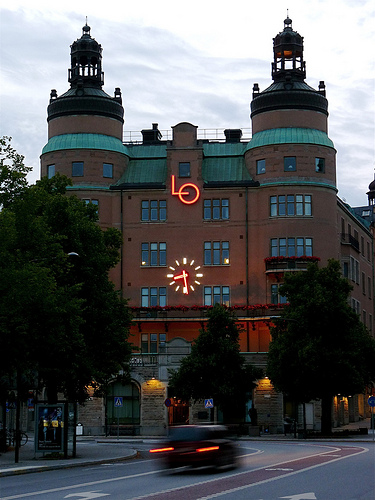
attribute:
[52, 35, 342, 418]
building — orange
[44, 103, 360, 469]
building — orange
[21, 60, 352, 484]
building — orange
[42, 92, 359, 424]
building — orange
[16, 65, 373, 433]
building — orange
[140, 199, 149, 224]
window — small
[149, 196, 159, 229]
window — small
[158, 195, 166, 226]
window — small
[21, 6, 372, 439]
building — orange, large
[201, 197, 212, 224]
window — small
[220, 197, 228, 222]
window — small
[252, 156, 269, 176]
window — small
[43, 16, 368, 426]
building — large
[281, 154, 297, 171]
window — small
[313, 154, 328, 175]
window — small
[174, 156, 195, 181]
window — small, large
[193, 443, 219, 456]
light — trailing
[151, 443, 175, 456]
light — trailing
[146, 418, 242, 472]
vehicle — red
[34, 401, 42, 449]
border — blue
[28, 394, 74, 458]
poster — large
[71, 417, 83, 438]
trash can — white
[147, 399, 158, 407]
bricks — black, white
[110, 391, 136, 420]
drapes — green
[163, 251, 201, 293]
clock — lighted, yellow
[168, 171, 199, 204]
logo — large, orange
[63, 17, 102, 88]
steeple — tall